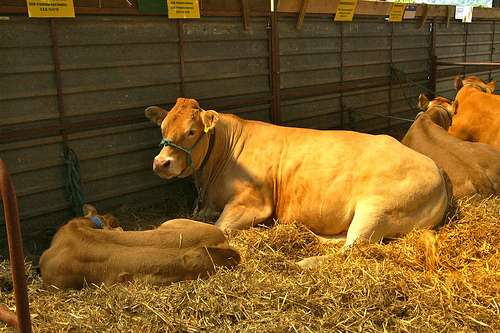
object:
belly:
[270, 186, 358, 236]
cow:
[398, 91, 499, 203]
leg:
[283, 203, 390, 273]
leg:
[212, 191, 272, 230]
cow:
[445, 73, 499, 151]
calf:
[40, 202, 242, 291]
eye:
[188, 128, 198, 137]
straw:
[178, 232, 184, 248]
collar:
[88, 215, 104, 227]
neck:
[76, 213, 106, 227]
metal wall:
[0, 0, 500, 258]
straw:
[0, 182, 500, 333]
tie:
[390, 67, 418, 115]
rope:
[63, 149, 85, 214]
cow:
[37, 203, 243, 295]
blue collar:
[160, 131, 211, 170]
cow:
[139, 90, 462, 272]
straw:
[204, 264, 496, 329]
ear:
[198, 109, 223, 133]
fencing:
[0, 0, 500, 249]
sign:
[25, 0, 79, 20]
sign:
[332, 0, 358, 22]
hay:
[0, 187, 500, 333]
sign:
[163, 0, 203, 22]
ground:
[0, 194, 500, 333]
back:
[67, 218, 228, 250]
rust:
[0, 0, 500, 245]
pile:
[297, 232, 500, 333]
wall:
[0, 0, 500, 249]